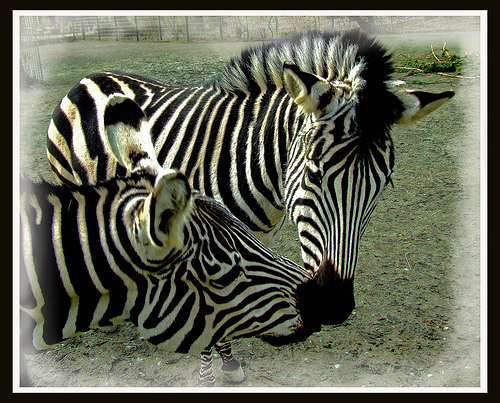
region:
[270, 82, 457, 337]
The zebra has black stripes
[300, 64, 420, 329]
the zebra has white stripes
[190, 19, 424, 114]
The zebra's hair is standing up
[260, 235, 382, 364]
the zebras are rubbing noses.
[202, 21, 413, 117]
this zebra has black hair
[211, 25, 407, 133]
this zebra has white hair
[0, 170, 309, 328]
this zebra has very little hair.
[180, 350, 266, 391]
this zebra has white feet.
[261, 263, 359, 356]
the zebras have black noses.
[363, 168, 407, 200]
this zebra has black eyelashes.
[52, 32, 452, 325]
black and white zebra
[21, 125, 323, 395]
zebra standing in grass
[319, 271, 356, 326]
black nose on zebra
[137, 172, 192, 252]
furry ear on zebra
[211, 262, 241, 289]
black eye on zebra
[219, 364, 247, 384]
white hoof on zebra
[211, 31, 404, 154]
black and white zebra mane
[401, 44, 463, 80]
tree branches on ground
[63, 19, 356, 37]
chain link barrier fence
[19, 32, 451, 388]
two zebra on grass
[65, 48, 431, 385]
two zebras with noses touching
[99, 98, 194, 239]
two big zebra ears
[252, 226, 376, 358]
two zebra noses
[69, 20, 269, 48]
fence behind two zebras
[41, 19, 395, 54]
long fence behind the zebras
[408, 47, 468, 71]
wood and bushes in the yard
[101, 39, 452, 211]
zebra and a mane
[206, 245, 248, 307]
big zebra eye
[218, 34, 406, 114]
black and white mane on a zebra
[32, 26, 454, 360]
The two zebras kissing.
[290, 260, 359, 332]
The zebras noses.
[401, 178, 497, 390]
The green grass.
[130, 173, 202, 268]
The left ear.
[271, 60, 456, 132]
The zebras right striped ear.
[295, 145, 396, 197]
The zebras eyes.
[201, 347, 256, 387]
The zebras two front legs.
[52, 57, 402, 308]
The zebra on the right.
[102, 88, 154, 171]
The zebras left ear.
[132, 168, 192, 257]
ear on zebra's head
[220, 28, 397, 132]
mane on zebra's neck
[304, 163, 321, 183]
eye on zebra's face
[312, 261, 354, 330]
snout on zebra's face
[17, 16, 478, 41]
wire fence running from one side to another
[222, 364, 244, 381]
hoof on zebra's body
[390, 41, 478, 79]
broken sticks in a pile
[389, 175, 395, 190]
eyelashes on zebra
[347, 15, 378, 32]
base of tree trunk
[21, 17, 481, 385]
ground surrounding zebras